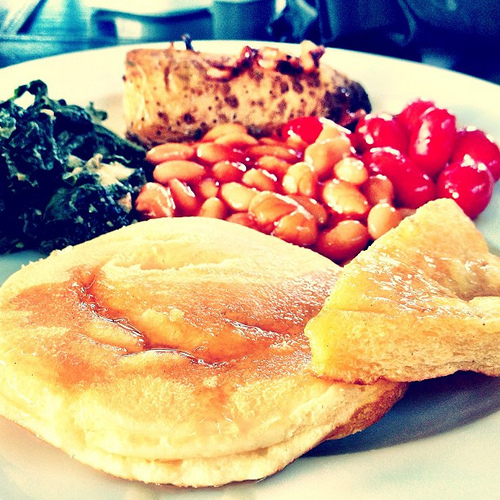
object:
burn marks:
[276, 57, 306, 82]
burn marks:
[339, 83, 366, 111]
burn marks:
[213, 46, 257, 78]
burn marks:
[217, 94, 241, 111]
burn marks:
[180, 113, 203, 134]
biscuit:
[391, 250, 453, 337]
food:
[3, 32, 498, 488]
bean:
[150, 124, 396, 237]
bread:
[303, 196, 499, 382]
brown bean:
[153, 130, 393, 245]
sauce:
[130, 96, 497, 265]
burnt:
[333, 81, 373, 114]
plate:
[0, 40, 500, 500]